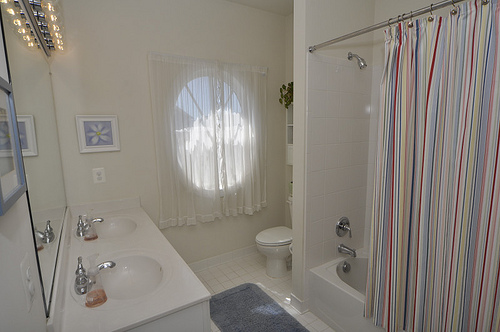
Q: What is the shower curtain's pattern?
A: Stripes.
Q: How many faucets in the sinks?
A: 2.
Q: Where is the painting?
A: On the wall.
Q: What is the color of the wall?
A: Cream.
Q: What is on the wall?
A: Mirror and picture.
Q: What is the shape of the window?
A: Oblong.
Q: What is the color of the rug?
A: Gray.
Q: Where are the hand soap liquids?
A: On the sink.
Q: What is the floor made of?
A: Tiles.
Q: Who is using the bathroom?
A: No one.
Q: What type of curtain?
A: A sheer curtain.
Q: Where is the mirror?
A: On the bathroom wall.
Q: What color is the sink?
A: White.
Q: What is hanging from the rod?
A: A shower curtain.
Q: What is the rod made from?
A: Metal.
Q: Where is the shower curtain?
A: Hanging from a rod.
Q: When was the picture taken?
A: Daytime.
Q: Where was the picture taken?
A: A bathroom.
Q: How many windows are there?
A: One.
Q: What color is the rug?
A: Blue.